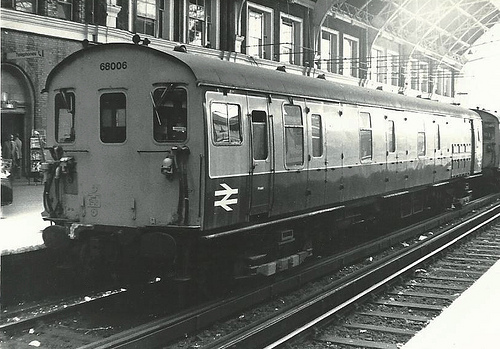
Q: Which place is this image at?
A: It is at the train station.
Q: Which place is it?
A: It is a train station.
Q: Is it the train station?
A: Yes, it is the train station.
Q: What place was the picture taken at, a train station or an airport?
A: It was taken at a train station.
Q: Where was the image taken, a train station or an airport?
A: It was taken at a train station.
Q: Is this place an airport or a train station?
A: It is a train station.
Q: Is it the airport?
A: No, it is the train station.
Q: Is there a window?
A: Yes, there is a window.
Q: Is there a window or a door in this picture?
A: Yes, there is a window.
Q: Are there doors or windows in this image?
A: Yes, there is a window.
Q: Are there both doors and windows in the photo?
A: Yes, there are both a window and a door.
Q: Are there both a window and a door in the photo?
A: Yes, there are both a window and a door.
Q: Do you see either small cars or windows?
A: Yes, there is a small window.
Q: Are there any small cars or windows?
A: Yes, there is a small window.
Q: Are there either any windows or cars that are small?
A: Yes, the window is small.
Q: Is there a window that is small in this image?
A: Yes, there is a small window.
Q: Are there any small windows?
A: Yes, there is a small window.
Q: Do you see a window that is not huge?
A: Yes, there is a small window.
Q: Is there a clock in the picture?
A: No, there are no clocks.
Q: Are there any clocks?
A: No, there are no clocks.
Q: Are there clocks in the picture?
A: No, there are no clocks.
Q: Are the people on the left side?
A: Yes, the people are on the left of the image.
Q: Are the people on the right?
A: No, the people are on the left of the image.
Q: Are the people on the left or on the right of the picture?
A: The people are on the left of the image.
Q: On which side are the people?
A: The people are on the left of the image.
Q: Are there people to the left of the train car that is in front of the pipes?
A: Yes, there are people to the left of the train car.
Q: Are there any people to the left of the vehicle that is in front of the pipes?
A: Yes, there are people to the left of the train car.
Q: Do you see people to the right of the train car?
A: No, the people are to the left of the train car.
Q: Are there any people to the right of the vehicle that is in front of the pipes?
A: No, the people are to the left of the train car.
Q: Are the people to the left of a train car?
A: Yes, the people are to the left of a train car.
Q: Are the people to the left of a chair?
A: No, the people are to the left of a train car.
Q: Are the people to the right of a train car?
A: No, the people are to the left of a train car.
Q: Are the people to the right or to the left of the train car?
A: The people are to the left of the train car.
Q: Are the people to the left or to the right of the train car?
A: The people are to the left of the train car.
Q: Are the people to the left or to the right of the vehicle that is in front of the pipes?
A: The people are to the left of the train car.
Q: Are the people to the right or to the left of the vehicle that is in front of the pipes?
A: The people are to the left of the train car.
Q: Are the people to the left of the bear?
A: Yes, the people are to the left of the bear.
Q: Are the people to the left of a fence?
A: No, the people are to the left of the bear.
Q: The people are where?
A: The people are at the train station.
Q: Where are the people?
A: The people are at the train station.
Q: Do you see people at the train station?
A: Yes, there are people at the train station.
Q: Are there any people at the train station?
A: Yes, there are people at the train station.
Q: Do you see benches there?
A: No, there are no benches.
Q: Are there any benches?
A: No, there are no benches.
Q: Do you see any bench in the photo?
A: No, there are no benches.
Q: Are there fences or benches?
A: No, there are no benches or fences.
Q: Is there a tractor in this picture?
A: No, there are no tractors.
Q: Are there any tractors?
A: No, there are no tractors.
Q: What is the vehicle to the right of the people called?
A: The vehicle is a train car.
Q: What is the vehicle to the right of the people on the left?
A: The vehicle is a train car.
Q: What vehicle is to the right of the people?
A: The vehicle is a train car.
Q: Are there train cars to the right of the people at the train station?
A: Yes, there is a train car to the right of the people.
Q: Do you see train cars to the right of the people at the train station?
A: Yes, there is a train car to the right of the people.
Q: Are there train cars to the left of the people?
A: No, the train car is to the right of the people.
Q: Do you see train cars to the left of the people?
A: No, the train car is to the right of the people.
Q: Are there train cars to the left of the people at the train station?
A: No, the train car is to the right of the people.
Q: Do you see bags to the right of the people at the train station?
A: No, there is a train car to the right of the people.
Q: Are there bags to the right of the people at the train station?
A: No, there is a train car to the right of the people.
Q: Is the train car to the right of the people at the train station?
A: Yes, the train car is to the right of the people.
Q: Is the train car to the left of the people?
A: No, the train car is to the right of the people.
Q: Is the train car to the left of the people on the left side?
A: No, the train car is to the right of the people.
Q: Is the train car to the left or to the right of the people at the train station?
A: The train car is to the right of the people.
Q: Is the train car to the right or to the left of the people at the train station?
A: The train car is to the right of the people.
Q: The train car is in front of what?
A: The train car is in front of the pipes.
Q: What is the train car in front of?
A: The train car is in front of the pipes.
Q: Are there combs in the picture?
A: No, there are no combs.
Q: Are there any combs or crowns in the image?
A: No, there are no combs or crowns.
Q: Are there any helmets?
A: No, there are no helmets.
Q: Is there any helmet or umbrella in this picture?
A: No, there are no helmets or umbrellas.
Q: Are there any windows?
A: Yes, there is a window.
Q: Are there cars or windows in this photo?
A: Yes, there is a window.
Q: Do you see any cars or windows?
A: Yes, there is a window.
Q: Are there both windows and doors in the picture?
A: Yes, there are both a window and a door.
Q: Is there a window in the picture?
A: Yes, there is a window.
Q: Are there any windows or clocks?
A: Yes, there is a window.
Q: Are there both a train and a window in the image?
A: Yes, there are both a window and a train.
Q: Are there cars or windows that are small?
A: Yes, the window is small.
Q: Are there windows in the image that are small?
A: Yes, there is a small window.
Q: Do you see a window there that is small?
A: Yes, there is a window that is small.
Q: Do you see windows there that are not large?
A: Yes, there is a small window.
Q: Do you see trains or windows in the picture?
A: Yes, there is a window.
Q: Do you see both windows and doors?
A: Yes, there are both a window and a door.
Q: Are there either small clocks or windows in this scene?
A: Yes, there is a small window.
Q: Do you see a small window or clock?
A: Yes, there is a small window.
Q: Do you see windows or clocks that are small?
A: Yes, the window is small.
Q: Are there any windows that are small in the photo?
A: Yes, there is a small window.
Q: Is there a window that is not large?
A: Yes, there is a small window.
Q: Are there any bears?
A: Yes, there is a bear.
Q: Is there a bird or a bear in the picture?
A: Yes, there is a bear.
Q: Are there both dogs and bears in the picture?
A: No, there is a bear but no dogs.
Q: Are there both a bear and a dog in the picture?
A: No, there is a bear but no dogs.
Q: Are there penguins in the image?
A: No, there are no penguins.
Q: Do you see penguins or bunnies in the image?
A: No, there are no penguins or bunnies.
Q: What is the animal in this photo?
A: The animal is a bear.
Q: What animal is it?
A: The animal is a bear.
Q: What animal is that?
A: That is a bear.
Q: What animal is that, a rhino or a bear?
A: That is a bear.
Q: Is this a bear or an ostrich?
A: This is a bear.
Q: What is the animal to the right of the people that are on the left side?
A: The animal is a bear.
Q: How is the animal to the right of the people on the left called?
A: The animal is a bear.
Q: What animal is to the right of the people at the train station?
A: The animal is a bear.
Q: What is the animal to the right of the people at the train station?
A: The animal is a bear.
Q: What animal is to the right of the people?
A: The animal is a bear.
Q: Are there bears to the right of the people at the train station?
A: Yes, there is a bear to the right of the people.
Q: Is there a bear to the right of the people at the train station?
A: Yes, there is a bear to the right of the people.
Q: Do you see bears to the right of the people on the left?
A: Yes, there is a bear to the right of the people.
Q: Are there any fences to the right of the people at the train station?
A: No, there is a bear to the right of the people.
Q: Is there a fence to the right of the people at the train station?
A: No, there is a bear to the right of the people.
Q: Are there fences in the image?
A: No, there are no fences.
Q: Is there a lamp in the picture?
A: No, there are no lamps.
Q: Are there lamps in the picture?
A: No, there are no lamps.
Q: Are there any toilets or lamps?
A: No, there are no lamps or toilets.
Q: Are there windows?
A: Yes, there is a window.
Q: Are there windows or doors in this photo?
A: Yes, there is a window.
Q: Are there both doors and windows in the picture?
A: Yes, there are both a window and a door.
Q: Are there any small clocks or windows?
A: Yes, there is a small window.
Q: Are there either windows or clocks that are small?
A: Yes, the window is small.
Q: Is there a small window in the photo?
A: Yes, there is a small window.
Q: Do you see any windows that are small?
A: Yes, there is a window that is small.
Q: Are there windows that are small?
A: Yes, there is a window that is small.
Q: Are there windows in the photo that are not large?
A: Yes, there is a small window.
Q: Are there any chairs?
A: No, there are no chairs.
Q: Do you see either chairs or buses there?
A: No, there are no chairs or buses.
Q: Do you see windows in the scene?
A: Yes, there is a window.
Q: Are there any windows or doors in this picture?
A: Yes, there is a window.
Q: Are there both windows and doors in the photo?
A: Yes, there are both a window and a door.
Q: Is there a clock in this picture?
A: No, there are no clocks.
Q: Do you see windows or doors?
A: Yes, there is a window.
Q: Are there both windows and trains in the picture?
A: Yes, there are both a window and a train.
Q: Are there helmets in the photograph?
A: No, there are no helmets.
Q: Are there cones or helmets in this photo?
A: No, there are no helmets or cones.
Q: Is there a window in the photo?
A: Yes, there is a window.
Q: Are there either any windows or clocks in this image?
A: Yes, there is a window.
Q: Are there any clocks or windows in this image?
A: Yes, there is a window.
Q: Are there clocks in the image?
A: No, there are no clocks.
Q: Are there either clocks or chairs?
A: No, there are no clocks or chairs.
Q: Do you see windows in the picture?
A: Yes, there is a window.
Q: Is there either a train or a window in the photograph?
A: Yes, there is a window.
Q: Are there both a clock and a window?
A: No, there is a window but no clocks.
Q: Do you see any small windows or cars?
A: Yes, there is a small window.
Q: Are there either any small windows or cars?
A: Yes, there is a small window.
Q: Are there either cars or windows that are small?
A: Yes, the window is small.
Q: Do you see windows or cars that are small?
A: Yes, the window is small.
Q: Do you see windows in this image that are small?
A: Yes, there is a small window.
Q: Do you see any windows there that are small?
A: Yes, there is a window that is small.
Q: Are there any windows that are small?
A: Yes, there is a window that is small.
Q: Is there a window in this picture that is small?
A: Yes, there is a window that is small.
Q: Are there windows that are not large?
A: Yes, there is a small window.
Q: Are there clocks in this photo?
A: No, there are no clocks.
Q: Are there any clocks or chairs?
A: No, there are no clocks or chairs.